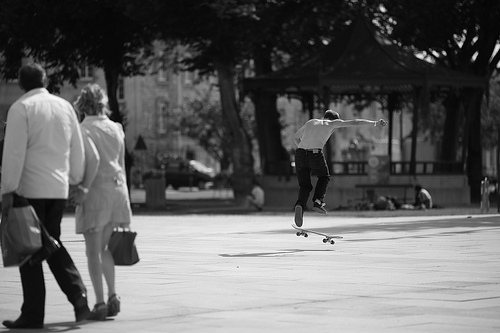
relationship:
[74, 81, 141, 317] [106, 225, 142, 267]
woman carrying bag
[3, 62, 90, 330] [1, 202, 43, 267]
man carrying bag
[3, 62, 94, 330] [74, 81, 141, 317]
man holding hand of woman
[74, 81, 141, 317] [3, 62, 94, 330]
woman holding hand of man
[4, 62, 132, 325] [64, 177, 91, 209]
couple holding hands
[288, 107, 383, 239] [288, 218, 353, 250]
man in skateboard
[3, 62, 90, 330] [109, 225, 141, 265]
man holding bag